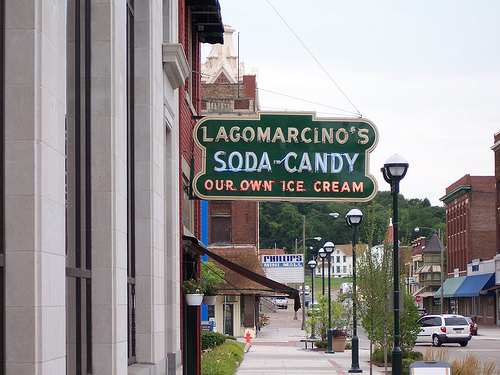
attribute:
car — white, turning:
[412, 313, 474, 348]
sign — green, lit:
[193, 109, 382, 205]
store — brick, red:
[179, 1, 203, 372]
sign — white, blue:
[260, 254, 307, 284]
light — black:
[380, 153, 410, 372]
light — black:
[346, 203, 366, 367]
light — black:
[319, 240, 335, 333]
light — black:
[319, 247, 327, 295]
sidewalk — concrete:
[231, 306, 393, 373]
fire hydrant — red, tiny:
[242, 330, 254, 350]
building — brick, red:
[444, 172, 500, 327]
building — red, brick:
[197, 24, 260, 334]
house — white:
[313, 243, 370, 280]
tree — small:
[366, 238, 428, 372]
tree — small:
[342, 201, 384, 373]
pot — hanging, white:
[179, 277, 206, 310]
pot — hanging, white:
[202, 283, 218, 310]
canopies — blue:
[432, 271, 496, 300]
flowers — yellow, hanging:
[183, 286, 208, 296]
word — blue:
[262, 249, 303, 265]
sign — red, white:
[414, 293, 429, 306]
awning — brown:
[177, 226, 304, 318]